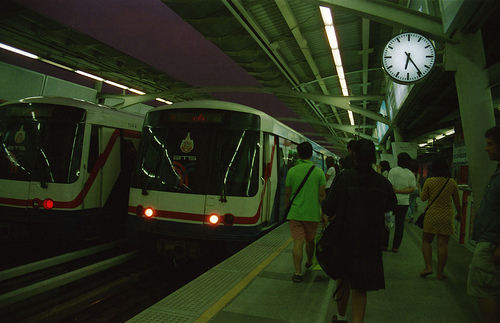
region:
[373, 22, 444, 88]
a white clock on roof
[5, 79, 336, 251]
two trains on the rails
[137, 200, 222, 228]
headlights are color red and white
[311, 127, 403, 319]
person wearing a black coat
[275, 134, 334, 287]
man wearing green shirt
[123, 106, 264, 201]
windshield of train is large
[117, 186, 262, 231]
a red stripe on front a train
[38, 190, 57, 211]
the light is color red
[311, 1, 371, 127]
lights on the ceiling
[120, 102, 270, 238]
The front of red and white subway car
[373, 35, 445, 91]
A modern style mounted wall clock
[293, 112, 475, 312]
Commuters on a subway platform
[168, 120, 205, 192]
A train logo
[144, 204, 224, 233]
Pair of glowing headlights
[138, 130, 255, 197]
Black train windshield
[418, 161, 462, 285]
Woman in dress with black purse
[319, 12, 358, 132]
Series of fluorescent lights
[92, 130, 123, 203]
Portion of side of a train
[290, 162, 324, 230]
Green shirt with black strap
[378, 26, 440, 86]
a clock on wall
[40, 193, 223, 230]
lights on train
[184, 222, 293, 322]
yellow strip on ground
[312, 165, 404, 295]
a black dress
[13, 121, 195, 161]
a symbol on windshield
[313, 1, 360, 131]
the lights in the ceiling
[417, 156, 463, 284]
a lady in peach dress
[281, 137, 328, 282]
a guy with shoulder bag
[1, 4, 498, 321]
the huge train station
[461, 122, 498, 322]
a man standing on the left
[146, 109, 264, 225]
a train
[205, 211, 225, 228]
a red light on the train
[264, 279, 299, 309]
the sidewalk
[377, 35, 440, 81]
a clock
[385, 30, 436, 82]
the clock is white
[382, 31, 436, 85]
the clock has black roman numerials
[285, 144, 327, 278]
a person walking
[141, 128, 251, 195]
a windshield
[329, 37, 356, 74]
a bright light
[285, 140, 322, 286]
commuter walking to their train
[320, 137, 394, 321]
commuter walking to their train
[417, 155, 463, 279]
commuter walking to their train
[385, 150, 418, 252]
commuter walking to their train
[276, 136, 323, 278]
a person walking on a sidewalk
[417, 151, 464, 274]
a person walking on a sidewalk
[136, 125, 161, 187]
train has a window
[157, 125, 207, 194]
train has a window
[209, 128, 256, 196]
train has a window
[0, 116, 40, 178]
train has a window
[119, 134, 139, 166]
train has a window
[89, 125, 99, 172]
train has a window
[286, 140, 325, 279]
person is walking in a station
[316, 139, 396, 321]
person is walking in a station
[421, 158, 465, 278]
person is walking in a station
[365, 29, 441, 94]
A hanging clock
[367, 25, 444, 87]
The hanging clock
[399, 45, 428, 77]
A set of hands on the clock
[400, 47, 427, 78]
The hands on the clock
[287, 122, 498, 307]
The people on the platform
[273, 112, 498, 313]
A set of people on the platform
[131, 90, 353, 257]
The train to the right